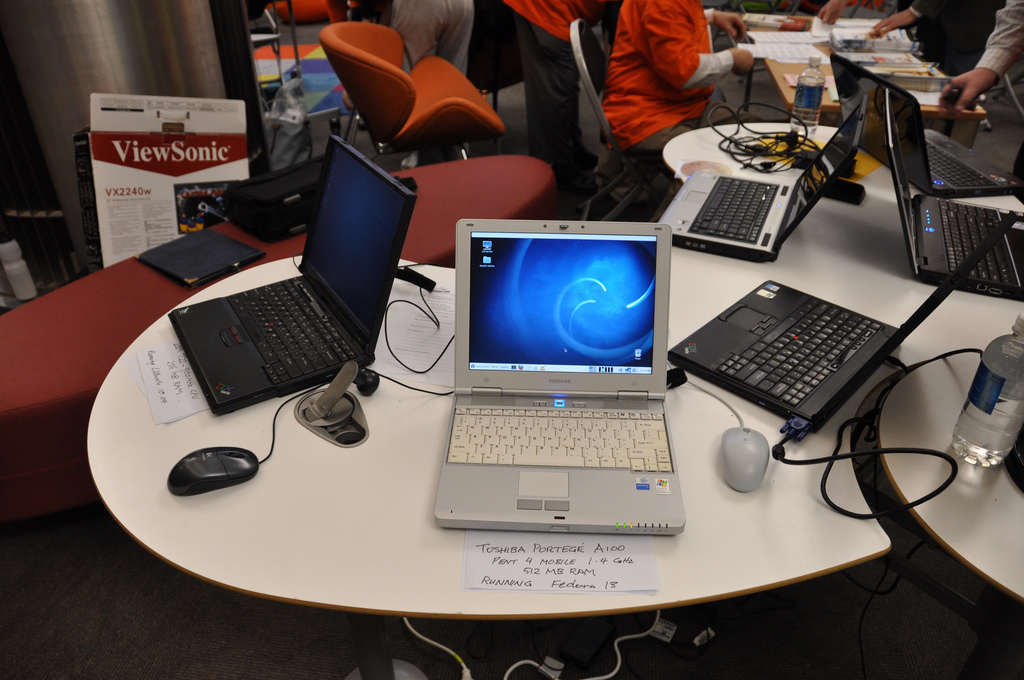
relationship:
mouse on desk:
[720, 431, 773, 494] [94, 120, 1004, 620]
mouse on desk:
[165, 447, 258, 497] [81, 222, 915, 618]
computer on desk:
[427, 209, 683, 536] [87, 217, 1012, 619]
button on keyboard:
[610, 438, 624, 449] [440, 403, 680, 468]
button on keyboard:
[561, 429, 577, 445] [450, 400, 680, 474]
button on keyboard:
[472, 429, 486, 445] [450, 400, 680, 474]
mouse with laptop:
[165, 447, 258, 497] [164, 122, 443, 427]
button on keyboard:
[623, 423, 645, 465] [450, 400, 680, 474]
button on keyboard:
[269, 328, 285, 346] [165, 276, 351, 419]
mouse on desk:
[111, 433, 248, 488] [258, 506, 362, 574]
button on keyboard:
[459, 400, 499, 444] [444, 376, 661, 515]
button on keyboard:
[574, 420, 670, 529] [478, 372, 692, 491]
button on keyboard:
[548, 449, 562, 463] [440, 403, 680, 468]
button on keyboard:
[606, 455, 619, 469] [448, 407, 671, 472]